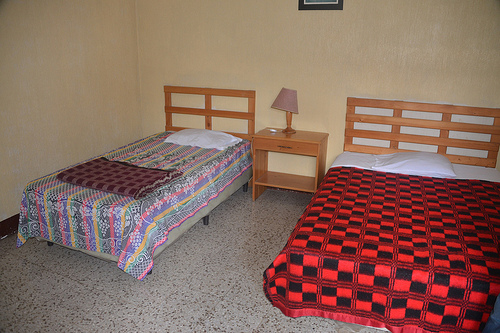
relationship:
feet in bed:
[201, 214, 215, 228] [15, 112, 257, 273]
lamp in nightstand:
[270, 86, 299, 134] [241, 110, 328, 205]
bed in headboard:
[264, 91, 499, 331] [336, 93, 498, 168]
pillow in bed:
[371, 150, 458, 179] [264, 91, 499, 331]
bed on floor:
[264, 91, 499, 331] [2, 185, 385, 329]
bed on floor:
[19, 88, 258, 281] [2, 185, 385, 329]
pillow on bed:
[162, 123, 242, 153] [19, 88, 258, 281]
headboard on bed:
[341, 96, 498, 168] [264, 91, 499, 331]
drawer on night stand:
[253, 138, 317, 153] [248, 127, 326, 199]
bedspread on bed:
[16, 131, 252, 281] [19, 88, 258, 281]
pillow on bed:
[378, 144, 458, 181] [290, 84, 491, 331]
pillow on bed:
[168, 121, 245, 149] [19, 88, 258, 281]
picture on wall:
[296, 0, 344, 10] [136, 2, 498, 174]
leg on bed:
[202, 212, 210, 225] [264, 91, 499, 331]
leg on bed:
[241, 181, 250, 193] [264, 91, 499, 331]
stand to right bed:
[238, 123, 335, 213] [278, 77, 461, 277]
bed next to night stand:
[1, 135, 261, 265] [247, 118, 307, 190]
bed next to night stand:
[282, 97, 500, 333] [251, 124, 328, 203]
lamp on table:
[270, 86, 299, 134] [267, 124, 314, 173]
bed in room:
[22, 83, 254, 275] [28, 64, 449, 309]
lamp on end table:
[270, 72, 304, 136] [247, 117, 327, 201]